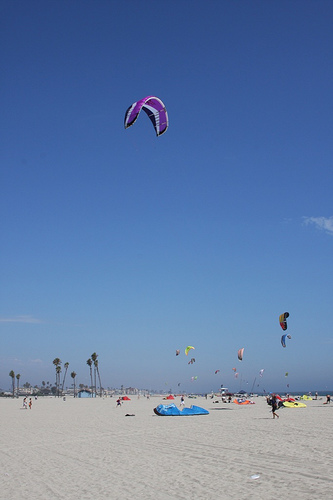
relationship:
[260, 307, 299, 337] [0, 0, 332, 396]
parasail in blue sky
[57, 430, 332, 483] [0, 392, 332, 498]
tracks in sand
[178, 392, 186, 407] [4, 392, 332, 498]
person walking on beach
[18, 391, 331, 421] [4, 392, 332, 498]
people on beach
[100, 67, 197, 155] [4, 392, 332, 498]
parachute laying down on beach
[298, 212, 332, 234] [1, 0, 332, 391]
white cloud in blue sky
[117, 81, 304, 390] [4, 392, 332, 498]
kites being flown over beach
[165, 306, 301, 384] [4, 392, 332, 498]
kites on beach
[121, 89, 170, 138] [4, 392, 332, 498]
kites on beach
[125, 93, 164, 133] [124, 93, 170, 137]
stripe on kite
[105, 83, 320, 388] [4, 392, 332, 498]
kites flying over beach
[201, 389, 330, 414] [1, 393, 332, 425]
beach goers in sand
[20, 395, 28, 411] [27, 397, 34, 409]
adult facing child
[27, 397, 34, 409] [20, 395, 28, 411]
child facing adult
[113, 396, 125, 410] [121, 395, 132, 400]
person running in front of kite